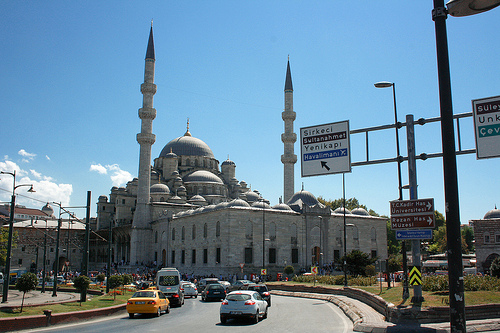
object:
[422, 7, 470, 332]
cart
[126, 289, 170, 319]
cab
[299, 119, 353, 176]
sign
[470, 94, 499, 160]
sign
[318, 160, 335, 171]
arrow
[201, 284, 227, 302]
car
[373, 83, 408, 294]
light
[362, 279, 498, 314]
grass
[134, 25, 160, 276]
tower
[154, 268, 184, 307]
bus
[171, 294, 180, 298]
break lights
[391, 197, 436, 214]
sign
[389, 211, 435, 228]
sign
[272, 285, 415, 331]
walkway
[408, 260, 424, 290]
sign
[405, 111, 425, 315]
pole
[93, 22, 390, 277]
building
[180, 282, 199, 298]
cars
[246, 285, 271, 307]
car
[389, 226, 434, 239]
sign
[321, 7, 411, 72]
wood table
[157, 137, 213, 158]
dome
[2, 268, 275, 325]
vehicles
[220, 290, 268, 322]
car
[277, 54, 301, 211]
tower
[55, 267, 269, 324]
traffic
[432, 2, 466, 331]
pole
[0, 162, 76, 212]
clouds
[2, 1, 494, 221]
sky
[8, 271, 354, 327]
road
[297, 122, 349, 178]
wall